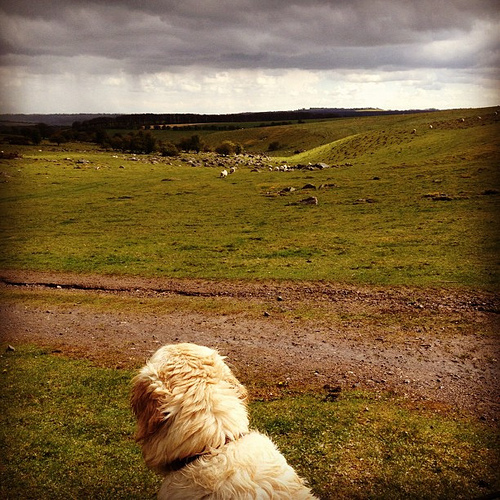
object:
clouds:
[0, 2, 499, 115]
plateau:
[273, 106, 383, 119]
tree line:
[0, 112, 115, 126]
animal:
[0, 109, 499, 182]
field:
[1, 103, 500, 499]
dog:
[128, 341, 319, 499]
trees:
[295, 111, 337, 116]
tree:
[217, 141, 248, 158]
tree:
[180, 133, 204, 153]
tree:
[44, 132, 77, 146]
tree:
[134, 129, 147, 145]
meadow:
[0, 103, 499, 499]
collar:
[150, 427, 267, 474]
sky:
[1, 0, 498, 113]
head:
[126, 340, 252, 459]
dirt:
[2, 267, 498, 427]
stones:
[275, 183, 321, 204]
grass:
[3, 109, 498, 499]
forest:
[0, 107, 440, 159]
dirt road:
[2, 271, 499, 450]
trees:
[143, 122, 153, 131]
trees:
[151, 121, 161, 131]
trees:
[160, 123, 166, 131]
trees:
[164, 125, 170, 132]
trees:
[168, 124, 177, 131]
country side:
[0, 101, 499, 499]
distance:
[0, 109, 499, 195]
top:
[0, 105, 445, 115]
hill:
[0, 104, 499, 272]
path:
[0, 259, 500, 430]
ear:
[124, 371, 165, 439]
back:
[157, 430, 316, 499]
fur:
[129, 340, 320, 500]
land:
[0, 104, 499, 498]